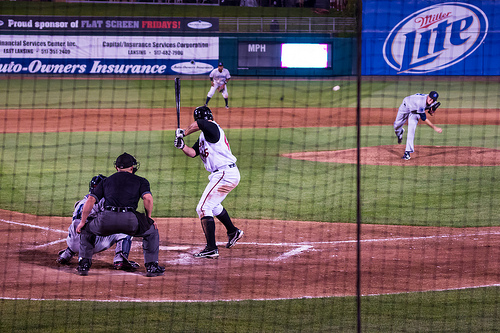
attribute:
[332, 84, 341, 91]
baseball — white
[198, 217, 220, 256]
black sock — tall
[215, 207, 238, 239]
black sock — tall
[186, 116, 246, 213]
uniform — white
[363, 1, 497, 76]
sign — Miller Lite 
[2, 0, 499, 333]
netting — black, protective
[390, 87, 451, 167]
pasta — short stop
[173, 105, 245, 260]
player — baseball player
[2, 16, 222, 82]
sign — blue, white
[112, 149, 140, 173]
cap — black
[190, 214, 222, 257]
sock — long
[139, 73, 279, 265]
player — baseball player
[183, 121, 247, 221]
uniform — white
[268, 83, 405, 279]
net — black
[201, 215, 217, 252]
sock — tall, black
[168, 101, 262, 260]
batter — left handed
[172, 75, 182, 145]
bat — blac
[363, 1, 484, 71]
millerlite sign — blue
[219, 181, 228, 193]
dirt — red